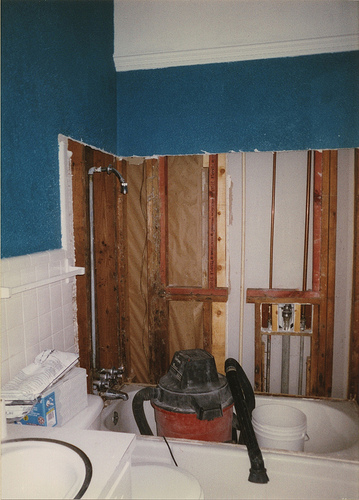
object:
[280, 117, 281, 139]
wall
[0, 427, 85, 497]
sink round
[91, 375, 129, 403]
faucet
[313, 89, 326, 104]
ground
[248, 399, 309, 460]
bucket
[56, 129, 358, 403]
shower wall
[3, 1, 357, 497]
room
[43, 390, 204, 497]
toilet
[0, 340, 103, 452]
items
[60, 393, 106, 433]
tank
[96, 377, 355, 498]
bathtub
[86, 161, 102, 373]
pipe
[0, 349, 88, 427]
package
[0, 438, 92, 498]
sink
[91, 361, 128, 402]
fixtures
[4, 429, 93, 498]
trim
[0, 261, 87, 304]
towel bar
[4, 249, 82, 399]
square tiles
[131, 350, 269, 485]
items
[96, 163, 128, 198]
shower head